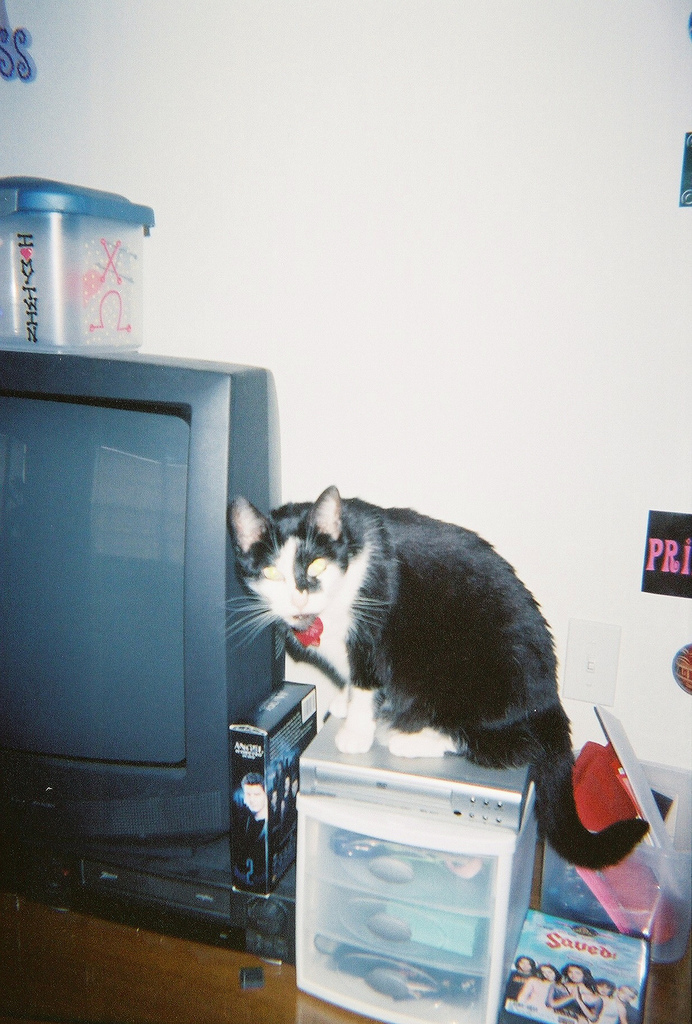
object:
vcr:
[1, 848, 303, 965]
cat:
[226, 479, 651, 874]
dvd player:
[295, 714, 542, 831]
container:
[0, 176, 155, 351]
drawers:
[291, 797, 538, 1022]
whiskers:
[211, 584, 392, 649]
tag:
[293, 616, 324, 648]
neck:
[278, 495, 381, 656]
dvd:
[490, 915, 650, 1022]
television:
[0, 350, 299, 846]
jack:
[562, 622, 622, 707]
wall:
[6, 2, 691, 787]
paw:
[335, 688, 377, 753]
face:
[254, 573, 332, 612]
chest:
[307, 627, 349, 674]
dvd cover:
[504, 944, 645, 1023]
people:
[547, 961, 601, 1024]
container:
[527, 751, 690, 961]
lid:
[583, 692, 668, 861]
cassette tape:
[238, 684, 310, 886]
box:
[225, 681, 323, 906]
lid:
[3, 169, 158, 219]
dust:
[240, 964, 263, 988]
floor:
[7, 722, 670, 1024]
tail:
[538, 745, 650, 868]